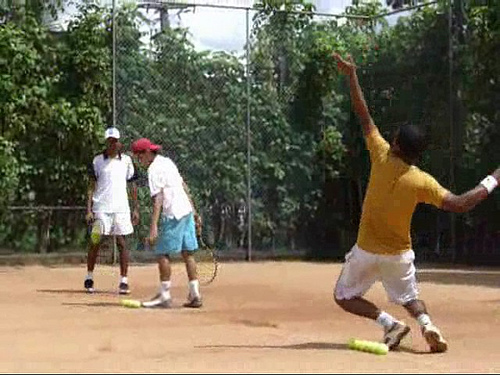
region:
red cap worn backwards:
[127, 132, 164, 159]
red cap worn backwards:
[131, 137, 165, 151]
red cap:
[135, 127, 175, 158]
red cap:
[107, 117, 182, 157]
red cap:
[97, 118, 169, 178]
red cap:
[78, 102, 169, 163]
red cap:
[52, 61, 184, 172]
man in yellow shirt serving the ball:
[329, 49, 499, 349]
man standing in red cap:
[130, 137, 212, 307]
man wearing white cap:
[84, 125, 136, 295]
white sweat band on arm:
[480, 171, 497, 194]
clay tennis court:
[0, 260, 492, 372]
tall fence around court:
[1, 0, 498, 265]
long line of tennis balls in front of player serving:
[345, 337, 387, 356]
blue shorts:
[157, 214, 197, 255]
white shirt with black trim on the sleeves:
[86, 152, 136, 214]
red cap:
[130, 137, 162, 152]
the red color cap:
[123, 131, 157, 156]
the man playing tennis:
[315, 34, 481, 359]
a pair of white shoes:
[380, 317, 450, 355]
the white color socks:
[372, 307, 406, 332]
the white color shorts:
[332, 230, 432, 311]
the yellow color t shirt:
[359, 126, 441, 276]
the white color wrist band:
[472, 170, 497, 192]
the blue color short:
[150, 208, 203, 262]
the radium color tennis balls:
[342, 326, 397, 368]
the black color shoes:
[110, 283, 134, 297]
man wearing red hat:
[128, 136, 160, 151]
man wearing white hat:
[103, 125, 121, 140]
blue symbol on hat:
[108, 125, 115, 139]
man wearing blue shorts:
[165, 227, 195, 247]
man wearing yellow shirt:
[376, 178, 404, 231]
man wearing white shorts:
[350, 261, 399, 281]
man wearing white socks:
[371, 306, 394, 330]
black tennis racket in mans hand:
[83, 218, 108, 248]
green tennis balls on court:
[336, 334, 392, 360]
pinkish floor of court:
[211, 316, 281, 347]